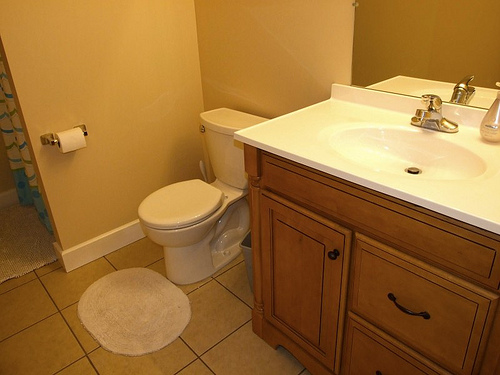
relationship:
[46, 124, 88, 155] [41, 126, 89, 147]
toilet paper in holder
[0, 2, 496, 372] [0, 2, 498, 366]
bathroom in area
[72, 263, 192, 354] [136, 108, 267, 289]
mat front toilet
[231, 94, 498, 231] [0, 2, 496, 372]
sink in bathroom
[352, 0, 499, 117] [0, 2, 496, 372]
mirror in bathroom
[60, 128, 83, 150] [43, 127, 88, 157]
roll on holder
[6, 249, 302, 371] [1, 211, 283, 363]
tile on floor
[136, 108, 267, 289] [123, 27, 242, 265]
toilet on corner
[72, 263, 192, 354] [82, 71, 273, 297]
mat front toilet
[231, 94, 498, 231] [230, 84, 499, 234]
sink on counter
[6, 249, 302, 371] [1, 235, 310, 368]
tile on floor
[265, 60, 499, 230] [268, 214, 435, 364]
sink on cabinet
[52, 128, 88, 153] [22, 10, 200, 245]
toilet paper hanging on wall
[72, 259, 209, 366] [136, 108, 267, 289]
mat in front of toilet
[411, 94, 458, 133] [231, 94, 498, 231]
faucet on sink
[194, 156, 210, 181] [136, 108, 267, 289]
toilet brush next to toilet